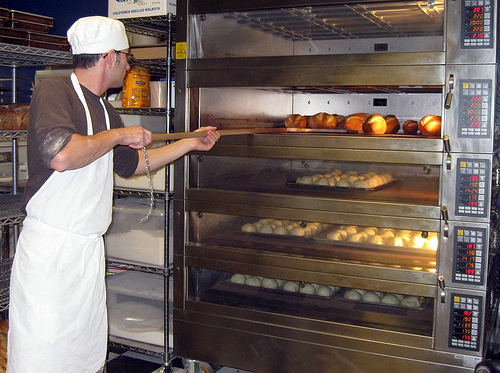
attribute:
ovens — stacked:
[176, 4, 498, 369]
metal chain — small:
[135, 144, 166, 227]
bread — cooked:
[283, 113, 443, 135]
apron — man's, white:
[4, 73, 118, 371]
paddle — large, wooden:
[126, 111, 362, 149]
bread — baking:
[226, 90, 438, 320]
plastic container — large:
[111, 268, 171, 325]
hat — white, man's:
[59, 10, 139, 75]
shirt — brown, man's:
[18, 74, 148, 234]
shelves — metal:
[201, 45, 488, 245]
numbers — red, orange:
[446, 4, 494, 354]